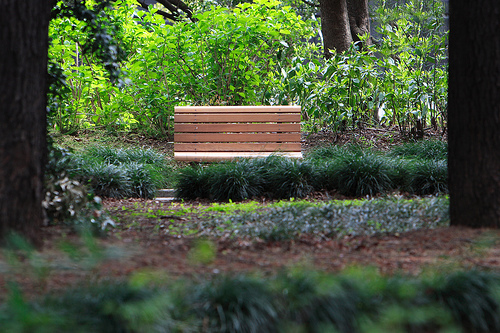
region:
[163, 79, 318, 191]
a wooden bench in a park.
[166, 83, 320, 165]
a wooden bench in a forest.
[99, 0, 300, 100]
a large green leafy bush.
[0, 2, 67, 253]
a very tall tree trunk.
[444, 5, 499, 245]
a tree trunk in a forest.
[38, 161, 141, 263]
a group of white flowers in a forest.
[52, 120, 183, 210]
a wild bush growing in a forest.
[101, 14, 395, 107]
a bunch of wild greener.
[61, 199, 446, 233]
a patch of wild flowers.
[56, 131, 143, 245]
wild plant growth.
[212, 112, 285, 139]
bench made of wood.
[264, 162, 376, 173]
plants in front of bench.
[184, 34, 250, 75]
plants behind the bench.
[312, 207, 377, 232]
flowers on the ground.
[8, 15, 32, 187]
trunk of the tree.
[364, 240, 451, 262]
dirt on the forest floor.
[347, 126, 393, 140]
sticks on the ground.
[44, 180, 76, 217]
leaves at the base of three.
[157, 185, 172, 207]
steps near the bench.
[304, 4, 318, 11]
branch sticking off the tree.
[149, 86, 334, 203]
wooden bench in park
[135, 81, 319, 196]
wooden bench with no one sitting on it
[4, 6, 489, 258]
tree trunks on either side of bench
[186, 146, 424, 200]
green grassy bushes in front of benches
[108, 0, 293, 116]
bright green plants behind bench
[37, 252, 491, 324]
foreground of picture blurry to accentuate bench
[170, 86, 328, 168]
wooden slats of bench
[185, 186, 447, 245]
small green plants covering ground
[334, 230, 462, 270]
path on ground in front of bench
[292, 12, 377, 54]
trees in the background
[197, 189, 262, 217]
green bush on ground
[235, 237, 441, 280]
rotting leaves on the ground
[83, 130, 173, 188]
large patch of green grass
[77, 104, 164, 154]
rotting branches on the ground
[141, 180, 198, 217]
steps in middle of bushes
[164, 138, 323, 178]
seat on brown bench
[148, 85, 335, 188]
large brown bench in middle of trees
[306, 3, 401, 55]
large black tree trunk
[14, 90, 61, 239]
lines in black tree trunk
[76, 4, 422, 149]
large cluster of green bushes and trees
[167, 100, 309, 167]
A brown wooden bench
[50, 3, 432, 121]
Green bushed behind bench.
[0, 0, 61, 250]
A tall tree trunk.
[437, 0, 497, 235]
A tall tree trunk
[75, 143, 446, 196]
Low green groundcover.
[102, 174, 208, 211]
A stone walkway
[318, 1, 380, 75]
Two brown tree trunks.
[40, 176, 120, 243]
A patch of groundcover at the base of a tree.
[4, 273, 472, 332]
A patch of blurry green groundcover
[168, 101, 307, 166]
A bench made for two people.